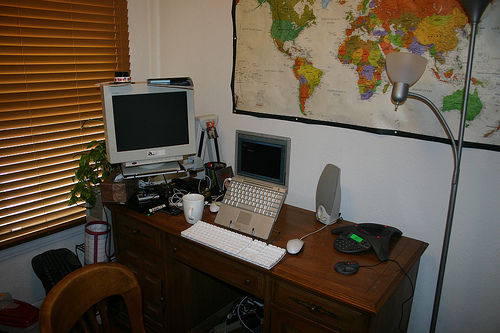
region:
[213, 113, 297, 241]
a silver laptop on a desk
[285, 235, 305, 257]
a mouse on a desk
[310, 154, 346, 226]
a speaker on a desk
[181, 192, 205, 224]
a mug on a desk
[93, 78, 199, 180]
a computer monitor on a desk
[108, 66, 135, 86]
a small black hat on a monitor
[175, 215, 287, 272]
a white keyboard on a desk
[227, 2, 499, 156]
a map of the world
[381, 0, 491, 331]
a tall metallic lamp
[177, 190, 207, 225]
A cup is sitting on a desk.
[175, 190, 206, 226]
The color of a cup is white.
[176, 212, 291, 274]
A keyboard is sitting on a desk.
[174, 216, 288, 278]
The color of a keyboard is white.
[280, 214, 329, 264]
A computer mouse is sitting on a desk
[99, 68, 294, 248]
Two computers are sitting on a desk.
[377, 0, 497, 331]
A lamp is next to a desk.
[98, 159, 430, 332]
The color of a desk is brown.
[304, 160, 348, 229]
A speaker is sitting on a desk.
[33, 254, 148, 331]
A brown chair is near a desk.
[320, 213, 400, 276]
The phone has a green light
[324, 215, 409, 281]
There is a phone on the desk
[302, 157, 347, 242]
There are speakers on the desk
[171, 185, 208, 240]
The cup is on the desk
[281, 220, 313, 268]
The computer mouse in of the desk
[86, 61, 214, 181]
The monitor is on the desk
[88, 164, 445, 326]
The desk is brown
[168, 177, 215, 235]
The cup is white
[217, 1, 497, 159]
There is a map on the wall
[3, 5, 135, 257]
There are blinds covering the window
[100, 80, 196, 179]
Bulky white computer screen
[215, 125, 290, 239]
Wide open silver laptop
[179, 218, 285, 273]
White computer keyboard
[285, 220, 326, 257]
White corded computer mouse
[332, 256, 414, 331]
Black corded computer mouse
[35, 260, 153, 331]
Brown desk chair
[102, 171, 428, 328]
Brown wood desk with drawers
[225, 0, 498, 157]
World map hanging on a wall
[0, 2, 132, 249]
Closed wood blinds on a window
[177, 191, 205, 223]
White coffee mug on a desk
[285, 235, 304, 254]
MOUSE ON THE DESK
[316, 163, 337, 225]
GREY SPEAKER ON THE DESK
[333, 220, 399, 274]
GAME SITTING ON THE DESK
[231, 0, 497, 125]
MAP ON THE WALL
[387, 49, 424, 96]
WHITE LIGHT ON A POLE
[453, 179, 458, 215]
POLE MADE OUT OF IRON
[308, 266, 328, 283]
DESK MADE OF WOOD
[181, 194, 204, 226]
COFFEE MUG ON THE TABLE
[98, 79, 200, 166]
large square black screen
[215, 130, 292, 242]
small square grey laptop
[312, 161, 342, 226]
small grey wide speaker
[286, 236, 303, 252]
small round white mouse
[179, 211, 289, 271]
long plastic white keyboard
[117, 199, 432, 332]
large wide wooden desk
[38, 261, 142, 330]
large short wooden chair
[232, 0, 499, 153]
large wide paper map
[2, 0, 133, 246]
large shaded brown window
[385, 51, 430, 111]
small white lamp shade